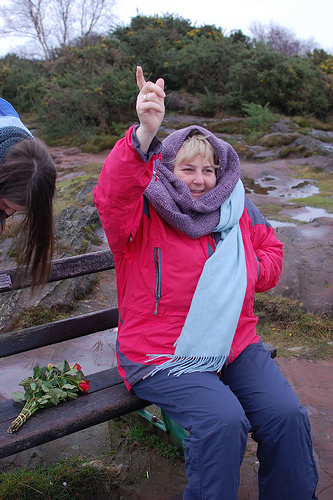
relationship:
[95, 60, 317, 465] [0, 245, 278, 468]
woman on a bench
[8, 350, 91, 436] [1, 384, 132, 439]
bouquet on a bench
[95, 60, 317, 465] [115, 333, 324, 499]
woman wearing blue pants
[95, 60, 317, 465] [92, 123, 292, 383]
woman wearing a jacket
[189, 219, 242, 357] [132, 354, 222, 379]
blue scarf with a fringe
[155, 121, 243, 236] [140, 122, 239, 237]
head in a purple scarf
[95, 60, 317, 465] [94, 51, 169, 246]
woman holding up her arm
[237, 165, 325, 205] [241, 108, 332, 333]
water on ground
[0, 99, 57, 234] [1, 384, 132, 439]
girl bending towards bench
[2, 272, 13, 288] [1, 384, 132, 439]
plaque on bench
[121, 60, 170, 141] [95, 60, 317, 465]
hand of a person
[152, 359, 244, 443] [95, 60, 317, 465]
thigh of a person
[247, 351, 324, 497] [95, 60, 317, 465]
leg of a person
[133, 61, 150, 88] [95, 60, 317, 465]
finger of a person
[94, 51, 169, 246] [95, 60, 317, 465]
arm of a person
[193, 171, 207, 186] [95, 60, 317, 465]
nose of a person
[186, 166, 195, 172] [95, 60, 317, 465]
eye of a person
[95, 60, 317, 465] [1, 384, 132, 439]
woman on a bench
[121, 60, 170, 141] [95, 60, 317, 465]
hand of a woman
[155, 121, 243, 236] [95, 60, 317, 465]
head of a woman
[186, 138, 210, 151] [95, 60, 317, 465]
hair of a woman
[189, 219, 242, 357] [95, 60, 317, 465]
blue scarf of a woman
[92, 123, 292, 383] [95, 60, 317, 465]
red jacket of a woman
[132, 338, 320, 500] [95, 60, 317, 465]
blue pants of a woman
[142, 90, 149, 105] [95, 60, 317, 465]
ring of a woman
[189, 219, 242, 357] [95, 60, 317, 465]
blue scarf around woman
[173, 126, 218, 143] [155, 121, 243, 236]
purple scarf around head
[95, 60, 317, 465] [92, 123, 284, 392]
woman wearing a jacket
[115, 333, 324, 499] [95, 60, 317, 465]
blue pants worn by a woman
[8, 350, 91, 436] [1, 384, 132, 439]
bouquet on bench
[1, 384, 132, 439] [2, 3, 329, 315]
bench in park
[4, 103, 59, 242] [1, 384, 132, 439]
girl leaning over bench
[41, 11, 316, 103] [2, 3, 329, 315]
trees in park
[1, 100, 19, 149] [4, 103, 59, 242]
blue scarf around girl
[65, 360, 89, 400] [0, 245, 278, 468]
flowers on bench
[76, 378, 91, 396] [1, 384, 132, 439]
flowers on bench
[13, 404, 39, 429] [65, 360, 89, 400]
rubber bands on flowers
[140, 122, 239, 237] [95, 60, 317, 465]
purple scarf around lady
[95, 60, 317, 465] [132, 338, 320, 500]
lady wearing blue pants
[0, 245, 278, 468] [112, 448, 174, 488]
bench in dirt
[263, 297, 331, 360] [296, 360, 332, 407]
grass in dirt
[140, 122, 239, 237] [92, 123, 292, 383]
purple scarf on a jacket